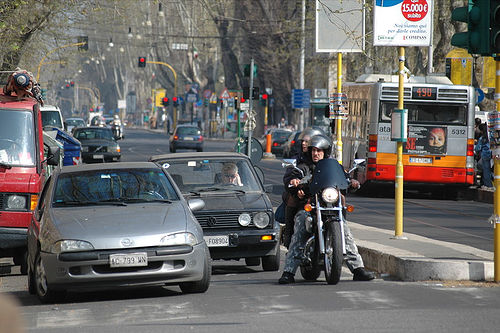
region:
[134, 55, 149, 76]
traffic light suspended on wire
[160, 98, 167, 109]
traffic light suspended on wire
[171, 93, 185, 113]
traffic light suspended on wire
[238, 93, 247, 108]
traffic light suspended on wire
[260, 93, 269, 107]
traffic light suspended on wire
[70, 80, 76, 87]
traffic light suspended on wire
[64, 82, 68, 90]
traffic light suspended on wire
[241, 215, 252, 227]
headlight on the car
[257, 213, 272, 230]
headlight on the car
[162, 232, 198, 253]
headlight on the car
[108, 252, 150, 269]
A license plate on a silver car.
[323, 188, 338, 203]
A headlight on a motorcycle.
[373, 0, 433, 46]
A sign on a pole.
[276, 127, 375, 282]
Two people on a motorcycle.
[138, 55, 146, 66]
The red light to a stop light.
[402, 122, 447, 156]
A sign on the back of a bus.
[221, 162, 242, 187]
A person sitting in a car.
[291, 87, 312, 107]
A blue road sign.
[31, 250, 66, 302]
A front tire on a car.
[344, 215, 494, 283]
A curb in the middle of the roadway.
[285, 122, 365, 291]
two people on a motorcycle at a traffic stop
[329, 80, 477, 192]
silver and red bus in the opposite lane of traffic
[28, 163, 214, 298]
small grey car stopped in traffic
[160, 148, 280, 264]
small black car stopped in traffic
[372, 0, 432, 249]
yellow pole holding up a sign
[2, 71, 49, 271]
the side of a large red vehicle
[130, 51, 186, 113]
three red stop lights in the distance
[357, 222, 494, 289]
grey cement median in the road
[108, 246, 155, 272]
white license plate on the front of the car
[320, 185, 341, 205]
round white headlight on the motorcycle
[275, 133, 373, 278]
Man wearing black helmet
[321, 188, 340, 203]
Round lit headlight on motorcycle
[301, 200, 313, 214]
Orange light on motorcycle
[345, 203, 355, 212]
Orange light on motorcycle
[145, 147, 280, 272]
Black car behind motorcycle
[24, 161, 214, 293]
Gray car next to motorcycle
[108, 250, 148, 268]
White license plate next to motorcycle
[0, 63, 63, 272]
Red truck behind gray car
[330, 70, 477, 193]
Large city bus is parked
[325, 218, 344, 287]
Black tire on motorcycle